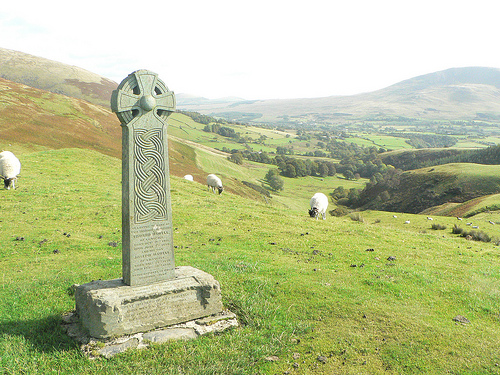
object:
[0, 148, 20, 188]
sheep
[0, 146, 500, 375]
grass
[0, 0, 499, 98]
sky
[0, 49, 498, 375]
ground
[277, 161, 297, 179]
trees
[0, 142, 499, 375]
hill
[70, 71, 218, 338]
epitaph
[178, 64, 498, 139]
hills